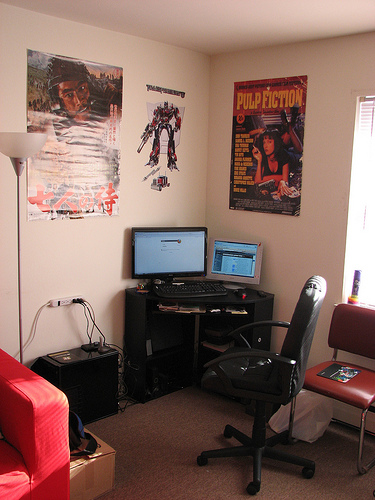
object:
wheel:
[244, 478, 261, 496]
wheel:
[300, 463, 315, 478]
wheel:
[196, 452, 209, 466]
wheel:
[223, 424, 235, 439]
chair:
[0, 345, 73, 499]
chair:
[287, 303, 375, 475]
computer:
[130, 225, 209, 285]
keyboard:
[152, 281, 230, 299]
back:
[277, 273, 327, 406]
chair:
[195, 273, 328, 496]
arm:
[203, 350, 297, 405]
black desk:
[125, 280, 275, 405]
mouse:
[241, 292, 248, 300]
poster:
[136, 84, 186, 191]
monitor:
[131, 227, 207, 280]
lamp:
[0, 131, 48, 365]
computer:
[32, 340, 132, 428]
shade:
[2, 133, 46, 164]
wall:
[0, 2, 375, 445]